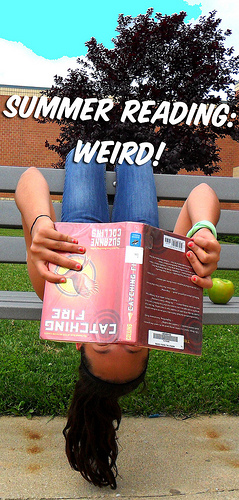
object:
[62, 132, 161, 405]
girl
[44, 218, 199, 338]
book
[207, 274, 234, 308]
apple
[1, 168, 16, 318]
bench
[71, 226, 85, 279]
nails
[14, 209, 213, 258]
bracelet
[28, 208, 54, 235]
wrist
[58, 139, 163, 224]
jeans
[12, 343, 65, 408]
grass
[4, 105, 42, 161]
wall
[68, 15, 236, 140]
tree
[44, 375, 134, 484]
hair